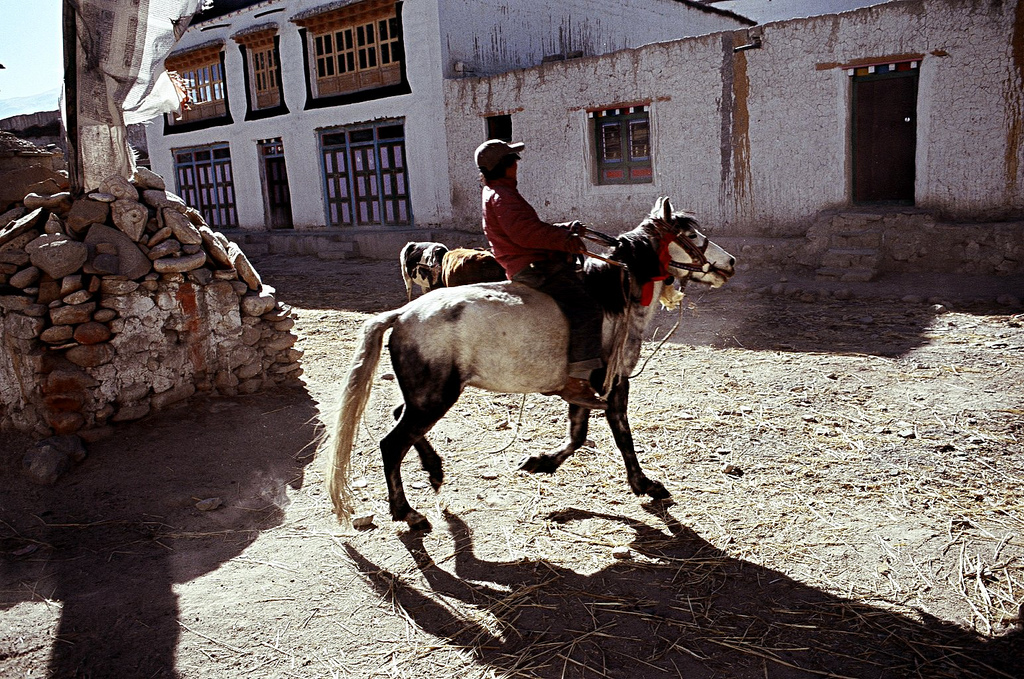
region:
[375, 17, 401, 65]
glass window pane on the building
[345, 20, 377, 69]
glass window pane on the building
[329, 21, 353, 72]
glass window pane on the building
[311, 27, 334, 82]
glass window pane on the building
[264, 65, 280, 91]
glass window pane on the building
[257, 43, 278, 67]
glass window pane on the building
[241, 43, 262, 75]
glass window pane on the building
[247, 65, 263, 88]
glass window pane on the building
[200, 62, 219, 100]
glass window pane on the building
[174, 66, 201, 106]
glass window pane on the building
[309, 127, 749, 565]
man riding a white horse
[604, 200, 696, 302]
black mane of the white horse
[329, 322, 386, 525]
white tail of the horse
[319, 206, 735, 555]
white and black horse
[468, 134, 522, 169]
hat the man is wearing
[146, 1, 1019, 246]
white building behind the horse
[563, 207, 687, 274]
reins the man is holding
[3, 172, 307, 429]
stones piled on top of each other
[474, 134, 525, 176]
Grey hat on a head.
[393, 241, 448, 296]
A black and white cow.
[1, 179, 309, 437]
A large pile of rocks.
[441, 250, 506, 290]
A brown cow back.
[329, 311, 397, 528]
A long white horse tail.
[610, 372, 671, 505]
Mostly black right horse leg touching the ground.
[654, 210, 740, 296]
Mostly white horses head.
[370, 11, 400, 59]
glass window pane on the building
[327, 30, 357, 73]
glass window pane on the building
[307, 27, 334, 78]
glass window pane on the building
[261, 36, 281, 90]
glass window pane on the building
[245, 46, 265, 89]
glass window pane on the building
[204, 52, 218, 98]
glass window pane on the building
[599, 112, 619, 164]
glass window pane on the building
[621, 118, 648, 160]
glass window pane on the building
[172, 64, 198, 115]
glass window pane on the building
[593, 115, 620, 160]
glass window on the building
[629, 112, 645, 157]
glass window on the building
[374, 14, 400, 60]
glass window on the building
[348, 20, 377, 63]
glass window on the building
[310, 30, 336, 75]
glass window on the building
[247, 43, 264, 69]
glass window on the building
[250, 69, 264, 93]
glass window on the building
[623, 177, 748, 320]
the head of a horse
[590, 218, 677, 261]
the mane of a horse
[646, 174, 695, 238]
the ears of a horse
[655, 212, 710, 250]
the eyes of a horse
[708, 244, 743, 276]
the nose of a horse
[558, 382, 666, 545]
the front legs of a horse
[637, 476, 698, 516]
the hoof of a horse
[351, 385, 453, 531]
the back legs of a horse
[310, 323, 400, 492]
the tail of a horse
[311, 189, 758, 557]
horse carrying person across land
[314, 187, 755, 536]
horse carrying person across land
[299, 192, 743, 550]
horse carrying person across land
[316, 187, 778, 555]
horse carrying person across land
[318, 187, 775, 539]
horse carrying person across land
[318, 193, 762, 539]
horse carrying person across land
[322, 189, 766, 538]
horse carrying person across land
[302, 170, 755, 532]
horse carrying person across land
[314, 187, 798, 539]
horse carrying person across land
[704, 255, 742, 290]
Mouth of a white horse